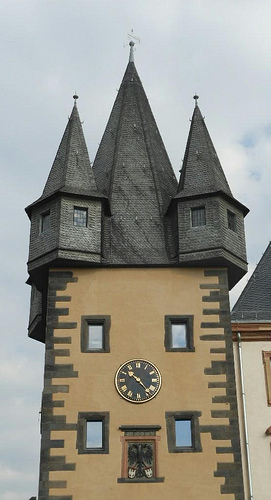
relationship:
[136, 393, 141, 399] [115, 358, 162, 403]
roman numeral on clock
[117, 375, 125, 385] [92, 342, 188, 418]
numeral on clock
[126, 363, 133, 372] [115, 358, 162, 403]
numeral on clock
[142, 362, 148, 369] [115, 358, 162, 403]
roman numeral on clock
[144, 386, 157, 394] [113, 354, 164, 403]
roman numeral on clock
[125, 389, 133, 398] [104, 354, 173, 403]
numeral on clock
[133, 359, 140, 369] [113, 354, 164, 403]
roman numeral on clock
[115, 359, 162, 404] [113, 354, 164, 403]
paper holder on clock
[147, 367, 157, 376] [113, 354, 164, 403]
roman numeral on clock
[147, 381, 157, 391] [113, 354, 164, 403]
roman numeral on clock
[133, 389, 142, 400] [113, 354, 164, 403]
roman numeral on clock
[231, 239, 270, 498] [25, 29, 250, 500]
building next to tower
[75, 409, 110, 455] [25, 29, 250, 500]
window on side of tower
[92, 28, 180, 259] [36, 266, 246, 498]
spire on top of building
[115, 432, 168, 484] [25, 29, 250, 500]
emblem on side of tower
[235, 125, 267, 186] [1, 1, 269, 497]
clouds in sky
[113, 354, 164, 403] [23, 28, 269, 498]
clock on tower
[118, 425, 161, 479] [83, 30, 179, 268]
emblem on tower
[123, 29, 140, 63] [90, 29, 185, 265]
tip on tower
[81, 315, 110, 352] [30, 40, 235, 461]
window on tower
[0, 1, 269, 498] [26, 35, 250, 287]
skys over tower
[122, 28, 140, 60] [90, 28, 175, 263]
tip on spire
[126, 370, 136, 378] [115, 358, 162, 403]
hand on clock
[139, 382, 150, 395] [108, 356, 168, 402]
minute hand on clock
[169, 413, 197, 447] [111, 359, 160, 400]
window below clock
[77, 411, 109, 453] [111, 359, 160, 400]
window below clock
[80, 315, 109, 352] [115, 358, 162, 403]
window above clock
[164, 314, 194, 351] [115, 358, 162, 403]
window above clock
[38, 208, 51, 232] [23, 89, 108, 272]
window on spire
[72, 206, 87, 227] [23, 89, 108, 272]
window on spire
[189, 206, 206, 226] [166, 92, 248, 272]
window on spire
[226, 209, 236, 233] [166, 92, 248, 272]
window on spire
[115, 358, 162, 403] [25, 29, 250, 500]
clock on tower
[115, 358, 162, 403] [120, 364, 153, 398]
clock says 10:22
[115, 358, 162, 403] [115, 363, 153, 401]
clock says 10:23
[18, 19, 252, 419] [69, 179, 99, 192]
tower has roof edge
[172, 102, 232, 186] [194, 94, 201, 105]
spire has tip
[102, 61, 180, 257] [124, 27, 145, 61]
spire has tip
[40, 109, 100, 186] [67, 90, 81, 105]
spire has tip